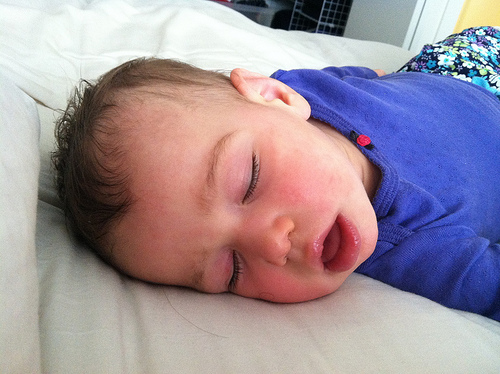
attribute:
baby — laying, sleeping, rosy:
[52, 24, 498, 296]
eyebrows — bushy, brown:
[181, 122, 233, 299]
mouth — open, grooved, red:
[307, 200, 361, 282]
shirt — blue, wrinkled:
[276, 44, 490, 311]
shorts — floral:
[398, 16, 499, 96]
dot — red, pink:
[352, 129, 374, 151]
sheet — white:
[0, 2, 463, 371]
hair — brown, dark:
[50, 50, 183, 274]